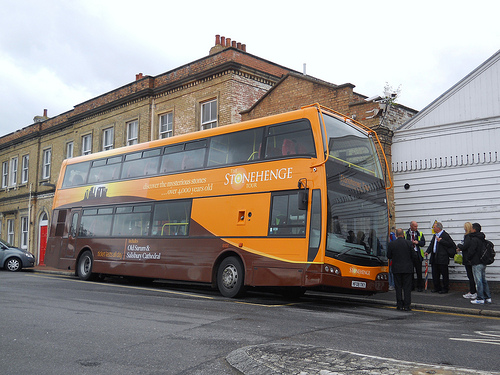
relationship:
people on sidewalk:
[386, 228, 417, 310] [306, 288, 499, 317]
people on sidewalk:
[401, 219, 427, 292] [306, 288, 499, 317]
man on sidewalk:
[423, 220, 451, 293] [306, 288, 499, 317]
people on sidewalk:
[455, 220, 476, 300] [306, 288, 499, 317]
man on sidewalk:
[463, 222, 496, 305] [306, 288, 499, 317]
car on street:
[0, 239, 36, 272] [2, 279, 497, 373]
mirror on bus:
[293, 176, 311, 215] [40, 101, 392, 298]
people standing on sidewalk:
[360, 202, 497, 337] [302, 282, 496, 318]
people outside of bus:
[360, 202, 497, 337] [40, 101, 392, 298]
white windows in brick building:
[191, 93, 221, 130] [3, 26, 298, 263]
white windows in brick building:
[150, 106, 180, 143] [3, 26, 298, 263]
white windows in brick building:
[121, 114, 138, 157] [3, 26, 298, 263]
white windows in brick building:
[98, 126, 117, 156] [3, 26, 298, 263]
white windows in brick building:
[76, 128, 98, 160] [3, 26, 298, 263]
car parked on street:
[0, 239, 38, 271] [0, 269, 498, 373]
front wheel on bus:
[216, 255, 244, 297] [40, 101, 392, 298]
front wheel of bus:
[217, 256, 238, 293] [42, 113, 385, 303]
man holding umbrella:
[423, 220, 456, 293] [422, 251, 429, 291]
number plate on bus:
[341, 268, 368, 288] [40, 101, 392, 298]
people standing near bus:
[386, 218, 483, 318] [53, 97, 430, 318]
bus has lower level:
[40, 101, 392, 298] [34, 183, 405, 303]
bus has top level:
[40, 101, 392, 298] [53, 102, 394, 192]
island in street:
[226, 341, 496, 373] [20, 287, 208, 362]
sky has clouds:
[1, 0, 499, 132] [0, 7, 152, 118]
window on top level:
[262, 120, 316, 159] [43, 108, 401, 213]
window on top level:
[206, 127, 266, 167] [43, 108, 401, 213]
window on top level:
[157, 136, 207, 173] [43, 108, 401, 213]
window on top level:
[118, 146, 161, 180] [43, 108, 401, 213]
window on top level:
[60, 160, 91, 190] [43, 108, 401, 213]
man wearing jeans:
[463, 214, 497, 303] [457, 254, 493, 299]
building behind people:
[386, 46, 493, 281] [382, 210, 498, 322]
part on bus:
[61, 107, 323, 182] [40, 101, 392, 298]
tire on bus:
[74, 248, 92, 280] [40, 101, 392, 298]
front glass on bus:
[325, 188, 386, 264] [40, 101, 392, 298]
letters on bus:
[224, 167, 294, 188] [40, 101, 392, 298]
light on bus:
[324, 263, 341, 280] [40, 101, 392, 298]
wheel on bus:
[217, 258, 249, 298] [40, 147, 400, 284]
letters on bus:
[226, 162, 297, 187] [35, 129, 391, 295]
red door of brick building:
[34, 228, 50, 268] [0, 33, 395, 265]